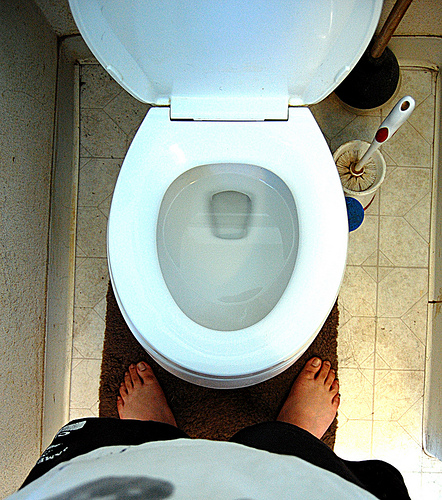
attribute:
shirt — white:
[36, 462, 332, 500]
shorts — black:
[48, 418, 167, 446]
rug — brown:
[101, 354, 125, 404]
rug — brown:
[98, 278, 343, 456]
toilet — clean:
[65, 0, 387, 390]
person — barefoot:
[2, 357, 411, 498]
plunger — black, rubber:
[335, 1, 419, 111]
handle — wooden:
[372, 1, 411, 59]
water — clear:
[163, 175, 295, 302]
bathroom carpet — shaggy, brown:
[98, 281, 339, 455]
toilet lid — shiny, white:
[67, 0, 386, 121]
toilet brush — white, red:
[336, 93, 415, 193]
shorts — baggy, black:
[18, 414, 410, 498]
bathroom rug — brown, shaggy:
[98, 278, 339, 451]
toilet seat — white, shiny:
[106, 108, 351, 378]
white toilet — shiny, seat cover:
[65, 0, 392, 392]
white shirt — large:
[2, 438, 390, 498]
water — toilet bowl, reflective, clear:
[181, 182, 276, 280]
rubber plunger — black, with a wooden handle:
[338, 44, 399, 110]